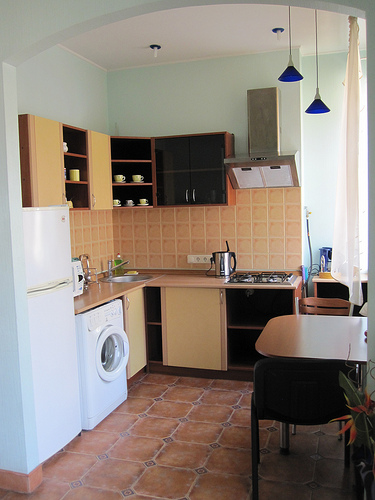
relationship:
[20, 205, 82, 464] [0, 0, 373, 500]
refrigerator in kitchen.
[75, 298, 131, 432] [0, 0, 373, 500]
dishwasher in kitchen.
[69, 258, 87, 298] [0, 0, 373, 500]
microwave in kitchen.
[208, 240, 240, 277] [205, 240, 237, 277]
silver coffee kettle.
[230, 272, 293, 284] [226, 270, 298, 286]
silver gas burners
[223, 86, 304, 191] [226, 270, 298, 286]
vents over burners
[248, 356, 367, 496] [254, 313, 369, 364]
chair by table.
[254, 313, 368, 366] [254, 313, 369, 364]
top. dining table.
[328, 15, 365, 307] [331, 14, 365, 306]
curtains covering windows.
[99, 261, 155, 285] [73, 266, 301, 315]
sink on counter.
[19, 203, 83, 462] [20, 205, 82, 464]
two door refrigerator.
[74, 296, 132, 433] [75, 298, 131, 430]
white washing dishwasher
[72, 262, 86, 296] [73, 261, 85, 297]
white control panel.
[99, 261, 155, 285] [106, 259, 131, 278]
sink and faucet.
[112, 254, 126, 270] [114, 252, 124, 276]
bright green bright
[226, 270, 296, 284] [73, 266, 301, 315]
burners in counter.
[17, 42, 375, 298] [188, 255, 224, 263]
wall electrical outlet.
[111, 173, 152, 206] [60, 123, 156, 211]
saucers on shelves.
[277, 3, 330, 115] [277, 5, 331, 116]
blue lights hanging.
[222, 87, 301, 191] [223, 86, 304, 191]
silver stove vent.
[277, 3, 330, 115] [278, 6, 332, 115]
blue light fixture.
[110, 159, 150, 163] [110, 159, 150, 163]
brown kitchen brown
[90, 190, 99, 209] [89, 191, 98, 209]
shelf door handles.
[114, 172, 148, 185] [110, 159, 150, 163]
teacups on brown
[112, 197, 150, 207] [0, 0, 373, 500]
teacups in kitchen.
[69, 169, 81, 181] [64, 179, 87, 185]
mug in shelf.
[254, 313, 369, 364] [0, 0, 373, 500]
table in kitchen.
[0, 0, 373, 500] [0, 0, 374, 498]
kitchen room scene.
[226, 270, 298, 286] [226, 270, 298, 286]
burners stove burners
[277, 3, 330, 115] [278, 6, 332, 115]
blue hanging lights.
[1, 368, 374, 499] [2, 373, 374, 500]
brown floor tiles.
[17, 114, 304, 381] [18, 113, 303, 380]
brown kitchen cabinet.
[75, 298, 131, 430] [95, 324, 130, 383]
dishwasher with door.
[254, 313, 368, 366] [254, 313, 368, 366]
top. table top.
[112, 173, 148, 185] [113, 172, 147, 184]
yellow tea mugs.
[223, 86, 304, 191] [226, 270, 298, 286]
range above burners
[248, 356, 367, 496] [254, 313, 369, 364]
chair at table.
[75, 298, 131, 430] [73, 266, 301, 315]
dishwasher under counter.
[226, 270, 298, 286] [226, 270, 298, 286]
burners burner burners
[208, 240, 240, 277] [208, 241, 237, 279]
silver water kettle.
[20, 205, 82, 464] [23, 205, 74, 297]
refrigerator and freezer.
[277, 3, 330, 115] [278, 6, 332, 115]
blue ceiling lights.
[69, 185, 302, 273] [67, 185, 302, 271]
tan tiled backsplash.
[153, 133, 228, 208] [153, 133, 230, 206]
cupboard with glass.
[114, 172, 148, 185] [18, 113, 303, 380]
teacups in cabinet.